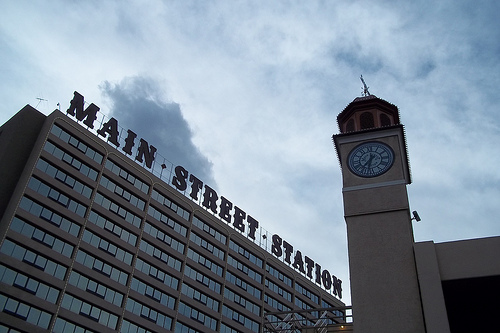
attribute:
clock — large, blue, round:
[345, 141, 396, 179]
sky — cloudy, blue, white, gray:
[0, 0, 500, 323]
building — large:
[0, 101, 345, 332]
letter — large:
[67, 89, 100, 130]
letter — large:
[96, 114, 121, 148]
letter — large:
[123, 128, 139, 158]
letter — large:
[135, 135, 158, 170]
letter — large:
[170, 165, 189, 191]